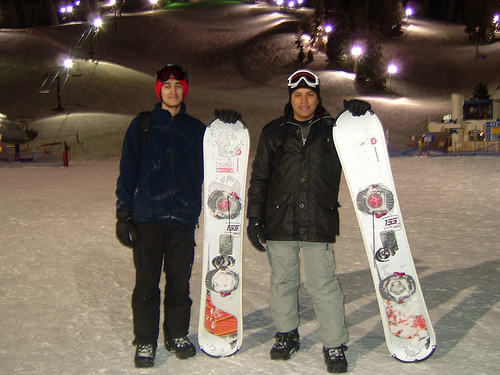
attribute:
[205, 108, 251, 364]
snowboard — long, slim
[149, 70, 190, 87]
hat — red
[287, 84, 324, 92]
hat — black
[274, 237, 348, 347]
pants — grey, gray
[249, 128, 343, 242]
jacket — black, thick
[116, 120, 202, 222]
jacket — blue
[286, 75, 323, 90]
goggles — white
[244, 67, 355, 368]
man — standing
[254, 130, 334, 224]
coat — black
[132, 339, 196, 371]
boots — black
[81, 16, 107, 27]
lights — glowing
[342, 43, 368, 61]
light — glowing, white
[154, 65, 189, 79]
eye gear — black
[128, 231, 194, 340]
pant — black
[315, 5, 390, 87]
tree — distance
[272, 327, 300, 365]
shoe — black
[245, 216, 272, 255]
gloves — black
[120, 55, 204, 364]
person — standing